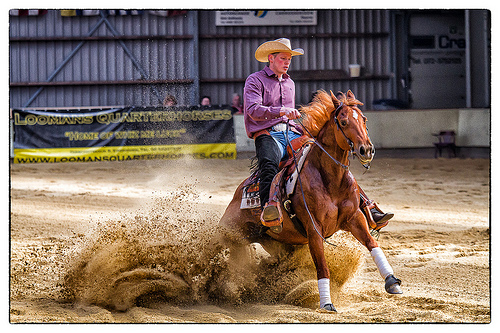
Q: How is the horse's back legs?
A: Bent.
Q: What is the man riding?
A: A horse.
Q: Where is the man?
A: An arena.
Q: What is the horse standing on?
A: Sand.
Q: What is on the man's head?
A: A hat.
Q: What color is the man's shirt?
A: Purple.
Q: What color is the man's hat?
A: Cream.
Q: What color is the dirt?
A: Tan.